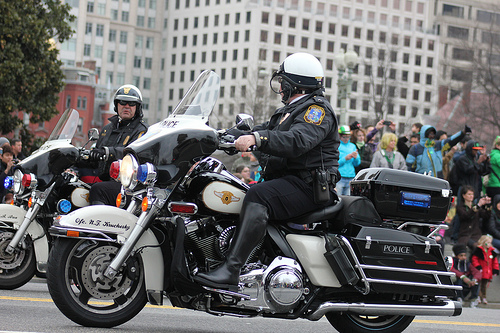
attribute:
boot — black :
[202, 199, 268, 294]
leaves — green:
[0, 1, 75, 130]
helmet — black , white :
[265, 45, 330, 103]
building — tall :
[38, 1, 498, 141]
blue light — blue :
[36, 191, 81, 230]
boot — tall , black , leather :
[193, 198, 270, 292]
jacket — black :
[247, 94, 340, 174]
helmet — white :
[274, 53, 315, 84]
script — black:
[71, 215, 136, 230]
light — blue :
[137, 164, 149, 183]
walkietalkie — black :
[311, 162, 334, 207]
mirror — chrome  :
[232, 112, 265, 129]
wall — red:
[58, 90, 93, 122]